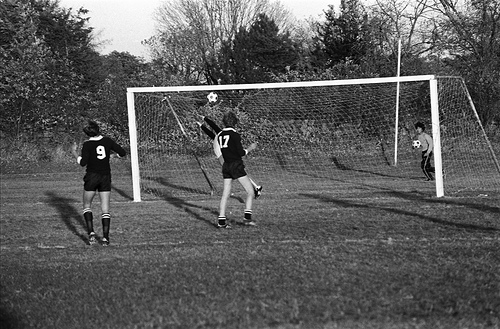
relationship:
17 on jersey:
[212, 133, 232, 150] [216, 130, 245, 160]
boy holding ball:
[412, 123, 435, 182] [394, 137, 428, 154]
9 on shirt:
[96, 146, 107, 160] [72, 133, 128, 174]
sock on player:
[102, 213, 111, 240] [73, 119, 124, 249]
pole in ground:
[96, 20, 458, 198] [46, 87, 455, 302]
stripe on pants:
[421, 151, 432, 181] [410, 146, 450, 191]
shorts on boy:
[81, 177, 113, 194] [213, 112, 254, 229]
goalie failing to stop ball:
[200, 118, 298, 223] [193, 84, 228, 112]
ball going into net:
[193, 84, 228, 112] [105, 62, 498, 229]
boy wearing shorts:
[71, 122, 126, 246] [200, 164, 280, 191]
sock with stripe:
[77, 205, 98, 240] [79, 205, 93, 212]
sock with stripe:
[97, 209, 114, 240] [99, 210, 114, 220]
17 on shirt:
[219, 135, 230, 148] [217, 129, 245, 157]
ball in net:
[207, 92, 218, 103] [129, 67, 490, 205]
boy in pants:
[408, 122, 447, 192] [417, 155, 431, 177]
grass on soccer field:
[0, 174, 500, 329] [0, 1, 498, 325]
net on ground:
[129, 67, 490, 205] [2, 142, 498, 327]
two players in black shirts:
[68, 110, 258, 247] [81, 130, 249, 173]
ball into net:
[207, 92, 218, 103] [134, 76, 500, 199]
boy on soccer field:
[71, 122, 126, 246] [0, 74, 499, 326]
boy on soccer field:
[412, 123, 435, 182] [0, 74, 499, 326]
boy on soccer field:
[213, 112, 254, 229] [0, 74, 499, 326]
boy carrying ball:
[412, 123, 435, 182] [400, 132, 427, 157]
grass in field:
[207, 249, 380, 321] [5, 152, 497, 327]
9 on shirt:
[96, 146, 107, 160] [178, 102, 280, 192]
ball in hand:
[410, 138, 420, 150] [409, 143, 421, 150]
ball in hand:
[410, 138, 420, 150] [422, 152, 429, 157]